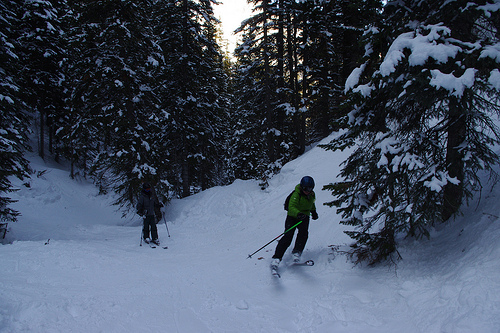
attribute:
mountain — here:
[1, 78, 496, 324]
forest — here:
[4, 2, 499, 259]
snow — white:
[38, 182, 318, 314]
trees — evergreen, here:
[19, 18, 469, 166]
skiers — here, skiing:
[124, 170, 339, 283]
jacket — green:
[287, 189, 317, 222]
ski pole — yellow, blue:
[159, 208, 175, 238]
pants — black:
[271, 210, 312, 264]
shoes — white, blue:
[267, 251, 306, 273]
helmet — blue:
[298, 174, 315, 188]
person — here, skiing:
[128, 165, 178, 254]